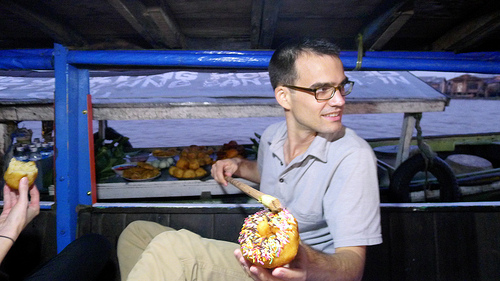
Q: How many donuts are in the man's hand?
A: One.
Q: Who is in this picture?
A: A man.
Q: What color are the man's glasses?
A: Black.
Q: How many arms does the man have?
A: Two.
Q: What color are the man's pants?
A: Tan.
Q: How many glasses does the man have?
A: One.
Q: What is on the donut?
A: Sprinkles.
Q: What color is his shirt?
A: Blue.